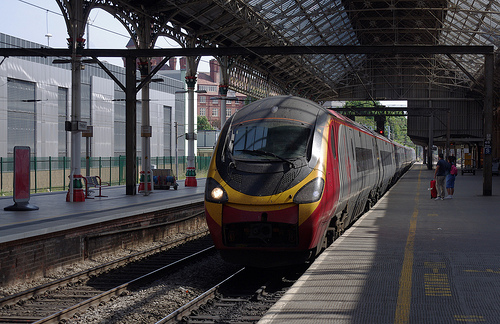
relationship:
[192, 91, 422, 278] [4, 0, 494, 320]
train on train stop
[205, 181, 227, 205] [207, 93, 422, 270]
headlight on train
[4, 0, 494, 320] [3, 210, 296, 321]
train stop on tracks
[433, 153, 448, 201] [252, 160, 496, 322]
man on side walk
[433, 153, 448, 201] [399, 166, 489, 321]
man on sidewalk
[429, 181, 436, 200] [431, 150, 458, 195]
bag on people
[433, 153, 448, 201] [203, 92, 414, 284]
man on train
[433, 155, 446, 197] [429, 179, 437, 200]
man on luggage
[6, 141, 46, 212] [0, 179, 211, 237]
sign on platform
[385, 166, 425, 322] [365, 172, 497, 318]
stripe on concrete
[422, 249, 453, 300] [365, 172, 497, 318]
words on concrete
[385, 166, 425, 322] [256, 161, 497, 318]
stripe on concrete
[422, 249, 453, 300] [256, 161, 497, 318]
words on concrete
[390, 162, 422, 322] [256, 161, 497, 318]
stripe on concrete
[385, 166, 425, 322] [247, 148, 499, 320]
stripe on concrete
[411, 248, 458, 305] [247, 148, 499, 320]
words on concrete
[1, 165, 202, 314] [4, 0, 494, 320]
platform at a train stop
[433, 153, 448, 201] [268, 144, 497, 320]
man standing on sidewalk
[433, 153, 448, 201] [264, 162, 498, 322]
man standing on sidewalk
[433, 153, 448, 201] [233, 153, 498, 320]
man standing on sidewalk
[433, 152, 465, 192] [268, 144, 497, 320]
people standing on sidewalk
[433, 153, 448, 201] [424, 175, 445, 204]
man with bag